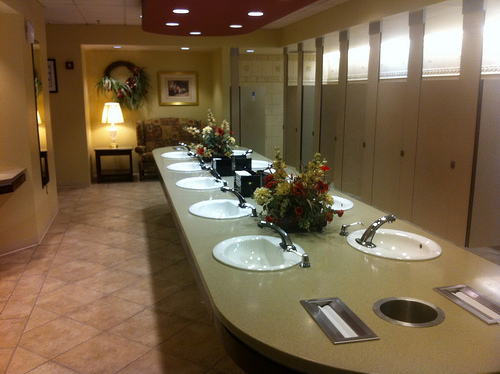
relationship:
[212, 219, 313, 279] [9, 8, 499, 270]
sink in room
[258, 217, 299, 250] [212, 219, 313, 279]
tap above sink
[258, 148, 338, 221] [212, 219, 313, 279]
flower by sink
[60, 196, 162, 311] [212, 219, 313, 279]
floor under sink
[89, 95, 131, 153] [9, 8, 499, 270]
lamp in room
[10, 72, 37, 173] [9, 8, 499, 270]
wall in room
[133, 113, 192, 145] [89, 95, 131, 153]
couch by lamp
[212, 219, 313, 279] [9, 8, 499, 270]
sink in bathroom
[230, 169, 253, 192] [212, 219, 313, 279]
towels are by sink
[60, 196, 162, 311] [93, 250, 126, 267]
floor has tiles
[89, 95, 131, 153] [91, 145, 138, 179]
lamp on table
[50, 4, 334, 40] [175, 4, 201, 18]
ceiling has lights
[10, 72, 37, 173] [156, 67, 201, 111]
wall has frame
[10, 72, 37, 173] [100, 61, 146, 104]
wall has wreath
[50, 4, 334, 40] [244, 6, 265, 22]
ceiling has light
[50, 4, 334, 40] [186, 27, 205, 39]
ceiling has light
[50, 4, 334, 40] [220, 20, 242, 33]
ceiling has light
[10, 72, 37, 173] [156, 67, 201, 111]
wall has art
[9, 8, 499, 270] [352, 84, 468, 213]
room has stalls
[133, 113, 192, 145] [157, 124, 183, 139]
sofa has patterns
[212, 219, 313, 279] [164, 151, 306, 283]
sink in row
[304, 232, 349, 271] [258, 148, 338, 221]
counter has flower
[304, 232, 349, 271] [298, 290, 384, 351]
counter has dispenser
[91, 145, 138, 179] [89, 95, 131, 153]
table has lamp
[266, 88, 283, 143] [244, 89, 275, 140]
stall has door